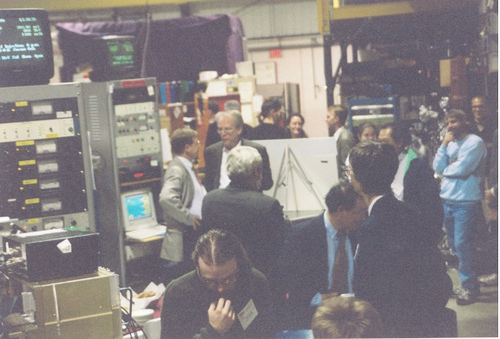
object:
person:
[434, 108, 488, 305]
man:
[161, 229, 275, 337]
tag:
[235, 298, 260, 331]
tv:
[0, 9, 54, 86]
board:
[242, 138, 341, 221]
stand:
[272, 146, 326, 218]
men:
[157, 93, 499, 338]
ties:
[224, 150, 238, 179]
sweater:
[434, 133, 488, 201]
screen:
[97, 35, 138, 83]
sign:
[268, 47, 283, 60]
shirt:
[325, 216, 356, 297]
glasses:
[200, 274, 242, 288]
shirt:
[175, 154, 210, 221]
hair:
[351, 138, 400, 195]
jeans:
[438, 200, 483, 291]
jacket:
[351, 143, 456, 338]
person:
[354, 196, 454, 338]